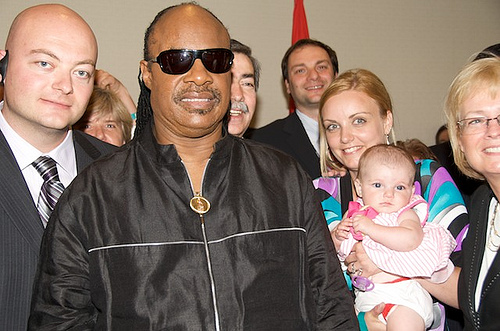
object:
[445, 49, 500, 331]
woman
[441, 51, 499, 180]
hair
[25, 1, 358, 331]
man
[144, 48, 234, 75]
sunglasses